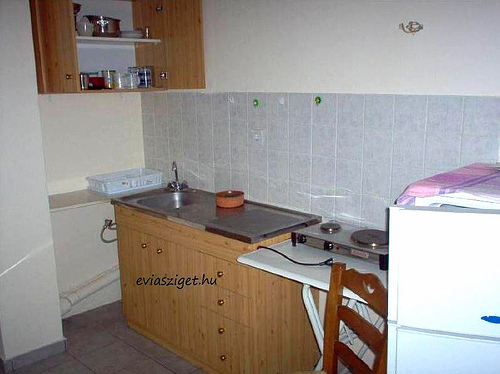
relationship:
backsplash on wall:
[148, 88, 459, 209] [204, 5, 489, 112]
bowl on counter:
[218, 183, 262, 219] [145, 173, 298, 247]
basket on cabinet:
[83, 167, 162, 196] [28, 1, 208, 94]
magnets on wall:
[247, 94, 332, 107] [204, 5, 489, 112]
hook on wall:
[383, 19, 435, 45] [204, 5, 489, 112]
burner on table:
[310, 217, 401, 266] [266, 221, 398, 303]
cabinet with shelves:
[33, 10, 197, 95] [70, 38, 164, 51]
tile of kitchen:
[57, 307, 148, 371] [5, 10, 487, 314]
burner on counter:
[289, 218, 400, 272] [289, 205, 373, 281]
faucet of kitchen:
[160, 166, 292, 230] [5, 10, 487, 314]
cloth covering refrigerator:
[420, 142, 476, 201] [387, 170, 500, 363]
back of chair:
[329, 269, 412, 372] [310, 251, 384, 372]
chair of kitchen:
[310, 251, 384, 372] [5, 10, 487, 314]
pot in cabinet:
[94, 16, 129, 45] [33, 10, 197, 95]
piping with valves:
[99, 214, 123, 243] [101, 220, 117, 231]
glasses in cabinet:
[141, 29, 154, 35] [33, 10, 197, 95]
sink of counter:
[141, 175, 205, 221] [145, 173, 298, 247]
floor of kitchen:
[67, 292, 147, 372] [0, 0, 500, 374]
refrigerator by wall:
[387, 170, 500, 363] [204, 5, 489, 112]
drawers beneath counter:
[198, 256, 247, 363] [145, 173, 298, 247]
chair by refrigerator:
[310, 251, 384, 372] [387, 170, 500, 363]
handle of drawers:
[216, 269, 229, 280] [198, 256, 247, 363]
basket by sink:
[99, 159, 165, 196] [141, 175, 205, 221]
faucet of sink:
[160, 166, 292, 230] [141, 175, 205, 221]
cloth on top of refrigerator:
[396, 160, 500, 209] [387, 170, 500, 363]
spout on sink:
[174, 159, 186, 181] [141, 175, 205, 221]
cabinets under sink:
[109, 204, 322, 368] [141, 175, 205, 221]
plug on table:
[307, 260, 336, 273] [266, 221, 398, 303]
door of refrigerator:
[395, 211, 493, 368] [387, 170, 500, 363]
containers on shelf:
[73, 11, 156, 50] [60, 15, 169, 97]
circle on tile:
[315, 94, 326, 109] [236, 81, 444, 229]